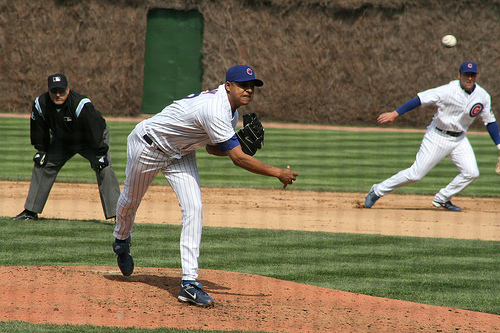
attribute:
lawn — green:
[4, 98, 497, 331]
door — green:
[139, 2, 207, 119]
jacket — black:
[20, 97, 95, 159]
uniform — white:
[110, 79, 243, 278]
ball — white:
[440, 34, 457, 50]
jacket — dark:
[14, 80, 116, 172]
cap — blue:
[217, 61, 290, 92]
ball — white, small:
[432, 20, 467, 62]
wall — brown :
[0, 2, 500, 133]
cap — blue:
[456, 47, 488, 141]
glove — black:
[234, 110, 266, 155]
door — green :
[142, 9, 208, 114]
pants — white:
[371, 126, 483, 198]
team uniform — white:
[375, 79, 493, 197]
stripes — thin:
[133, 148, 151, 182]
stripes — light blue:
[73, 91, 98, 118]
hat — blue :
[221, 47, 268, 90]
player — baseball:
[351, 64, 483, 233]